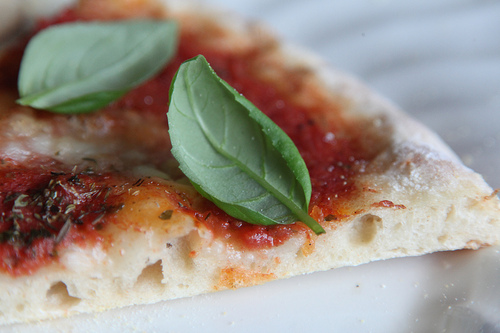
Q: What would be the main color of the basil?
A: Green.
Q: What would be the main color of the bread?
A: Tan.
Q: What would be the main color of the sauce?
A: Red.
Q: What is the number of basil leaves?
A: 2.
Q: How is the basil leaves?
A: Upside down.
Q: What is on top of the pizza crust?
A: Tomato sauce.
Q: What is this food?
A: Pizza.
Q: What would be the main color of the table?
A: White.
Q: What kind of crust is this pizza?
A: Thin crust.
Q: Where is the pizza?
A: On the plate.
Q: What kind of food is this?
A: Pizza.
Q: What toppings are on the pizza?
A: Tomato sauce and basil.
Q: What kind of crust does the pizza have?
A: Thin crust.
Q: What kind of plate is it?
A: White with curled edges.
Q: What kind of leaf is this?
A: Basil.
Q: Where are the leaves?
A: On the pizza.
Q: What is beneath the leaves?
A: Pizza.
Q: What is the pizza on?
A: A shiny table.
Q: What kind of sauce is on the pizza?
A: Tomato.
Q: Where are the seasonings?
A: On the pizza.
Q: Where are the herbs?
A: By the leaves.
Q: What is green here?
A: Leaf.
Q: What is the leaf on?
A: Pizza.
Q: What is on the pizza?
A: A leaf.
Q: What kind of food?
A: Pizza.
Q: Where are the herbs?
A: On the pizza.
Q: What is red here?
A: Pizza sauce.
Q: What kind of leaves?
A: Basil.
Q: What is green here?
A: Two leaves.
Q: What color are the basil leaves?
A: Green.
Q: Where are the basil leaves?
A: On the photo.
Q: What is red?
A: Tomato sauce.